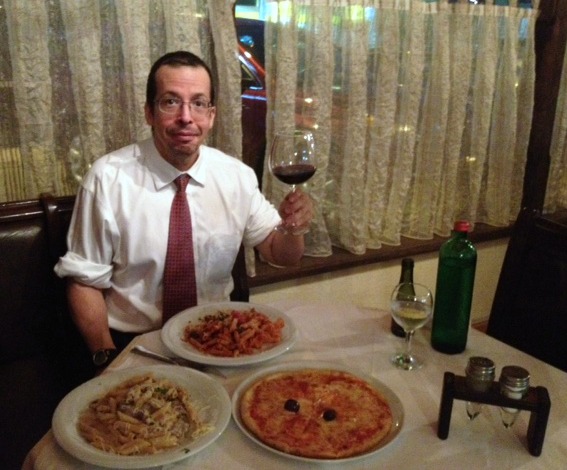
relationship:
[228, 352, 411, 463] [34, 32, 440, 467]
plate for dining